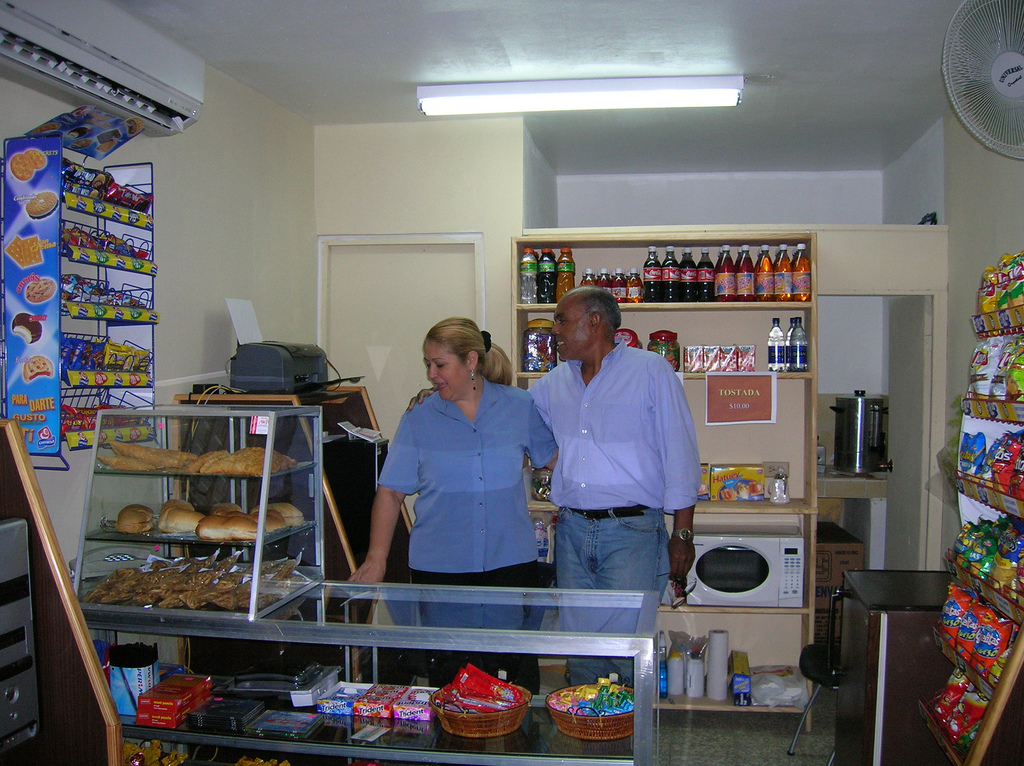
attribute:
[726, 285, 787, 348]
bottle — orange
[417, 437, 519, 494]
body — woman's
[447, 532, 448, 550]
part — body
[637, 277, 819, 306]
bottle — on the shelf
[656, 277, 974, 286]
bottle — on the shelf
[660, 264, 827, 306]
bottle — on the shelf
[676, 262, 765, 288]
bottle — on the shelf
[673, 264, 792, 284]
bottle — on the shelf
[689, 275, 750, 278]
bottle — on the shelf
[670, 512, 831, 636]
microwave — white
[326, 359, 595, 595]
shirt — blue, buttoned up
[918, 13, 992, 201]
fan — white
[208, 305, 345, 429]
printer — dark grey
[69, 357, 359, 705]
case — display, glass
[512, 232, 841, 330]
drinks — bottled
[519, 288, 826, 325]
shelf — light colored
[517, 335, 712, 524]
button down — blue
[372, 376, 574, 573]
blouse — blue